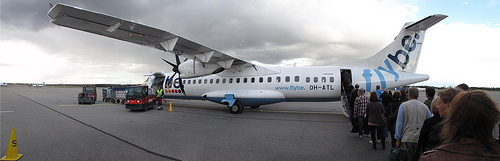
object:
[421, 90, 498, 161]
people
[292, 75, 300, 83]
windows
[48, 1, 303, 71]
wings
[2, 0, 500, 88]
sky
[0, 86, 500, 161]
tarmac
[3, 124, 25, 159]
cone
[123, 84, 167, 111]
truck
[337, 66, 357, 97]
door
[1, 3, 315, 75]
clouds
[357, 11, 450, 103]
tail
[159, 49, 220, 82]
engine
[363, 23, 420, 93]
words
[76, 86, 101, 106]
vehicles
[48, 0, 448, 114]
plane